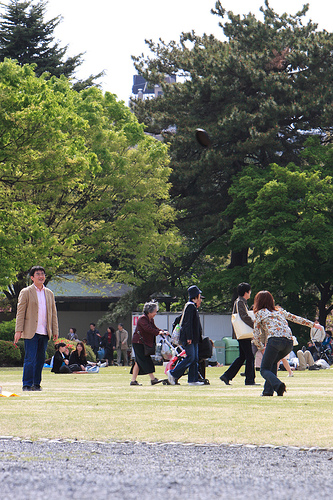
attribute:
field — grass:
[3, 365, 331, 446]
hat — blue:
[182, 276, 207, 308]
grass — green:
[2, 361, 331, 440]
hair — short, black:
[23, 264, 48, 278]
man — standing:
[14, 262, 65, 398]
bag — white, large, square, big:
[225, 307, 261, 342]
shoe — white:
[164, 364, 184, 387]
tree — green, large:
[2, 58, 192, 318]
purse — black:
[195, 333, 220, 366]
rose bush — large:
[0, 335, 32, 371]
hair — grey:
[139, 298, 160, 318]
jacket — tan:
[8, 282, 61, 343]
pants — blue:
[21, 336, 53, 392]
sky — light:
[12, 1, 298, 97]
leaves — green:
[4, 106, 138, 229]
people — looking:
[17, 267, 333, 389]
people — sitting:
[44, 330, 100, 375]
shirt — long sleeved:
[246, 303, 319, 363]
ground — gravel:
[2, 438, 332, 499]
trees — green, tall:
[4, 3, 329, 314]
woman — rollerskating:
[247, 293, 326, 395]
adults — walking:
[115, 282, 218, 393]